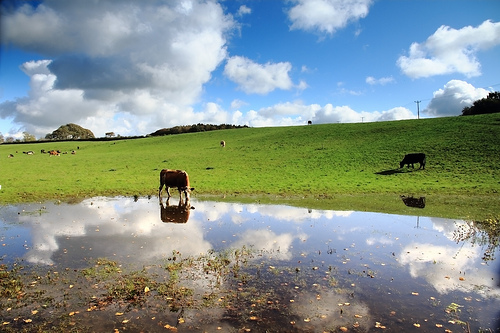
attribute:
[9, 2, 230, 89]
clouds — white 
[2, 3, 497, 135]
sky — blue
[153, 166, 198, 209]
cow — brown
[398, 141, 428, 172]
cow — black, grazing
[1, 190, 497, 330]
puddle — large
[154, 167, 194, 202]
cow — brown, drinking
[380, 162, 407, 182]
shadow — black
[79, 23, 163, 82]
clouds — white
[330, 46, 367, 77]
sky — blue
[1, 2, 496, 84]
sky — blue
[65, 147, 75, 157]
cows — distant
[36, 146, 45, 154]
cows — distant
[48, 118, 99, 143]
tree — large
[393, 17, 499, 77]
cloud — white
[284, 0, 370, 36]
cloud — white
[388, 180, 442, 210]
cow — black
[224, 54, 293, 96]
clouds — white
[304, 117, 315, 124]
cow — standing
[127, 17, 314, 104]
clouds — white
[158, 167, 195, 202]
cow — brown 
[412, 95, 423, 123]
pole — utility, distant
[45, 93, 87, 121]
clouds — white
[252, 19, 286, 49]
sky — blue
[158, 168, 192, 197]
cow — drinking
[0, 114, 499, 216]
grass — short, green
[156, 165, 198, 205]
cow — brown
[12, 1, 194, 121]
clouds — white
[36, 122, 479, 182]
hill — grass covered